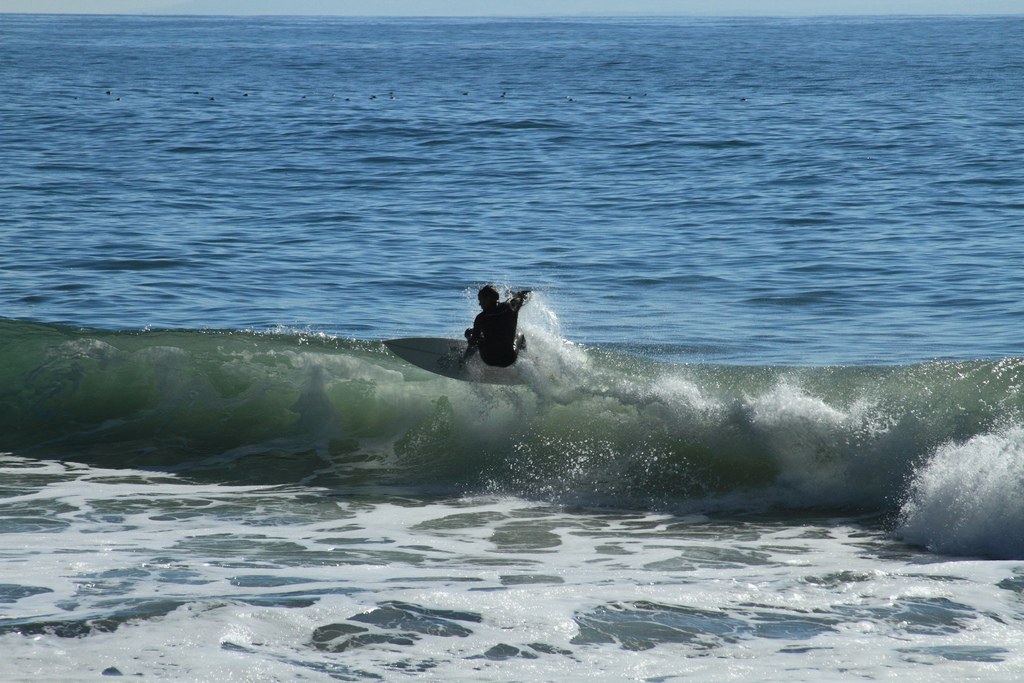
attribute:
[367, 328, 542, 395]
surfboard — large, blue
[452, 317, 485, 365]
arm — long , thin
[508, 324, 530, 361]
leg — long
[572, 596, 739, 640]
water — gray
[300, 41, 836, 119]
birds — distant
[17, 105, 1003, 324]
waves — coming in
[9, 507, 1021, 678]
sea foam — stirred up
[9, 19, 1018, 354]
water — calm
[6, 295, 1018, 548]
wave — green, large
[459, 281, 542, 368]
person — surfing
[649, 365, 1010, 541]
wave — rolling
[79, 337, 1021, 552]
waves — white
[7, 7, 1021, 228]
ocean — calm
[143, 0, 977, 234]
water — blue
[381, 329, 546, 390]
surfboard — white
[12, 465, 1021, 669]
part — foamy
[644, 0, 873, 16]
patch — small, blue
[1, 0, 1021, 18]
sky — clear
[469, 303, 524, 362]
wetsuit — black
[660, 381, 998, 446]
top — foamy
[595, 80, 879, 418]
ocean — calm